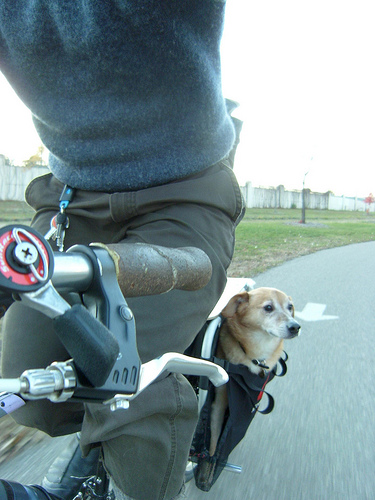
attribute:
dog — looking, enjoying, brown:
[220, 274, 295, 402]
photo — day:
[28, 11, 371, 475]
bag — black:
[189, 375, 276, 460]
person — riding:
[24, 31, 240, 307]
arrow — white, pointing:
[286, 281, 361, 345]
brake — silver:
[39, 340, 230, 395]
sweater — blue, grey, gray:
[16, 10, 214, 162]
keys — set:
[19, 171, 81, 262]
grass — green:
[246, 212, 370, 255]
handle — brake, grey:
[41, 236, 239, 312]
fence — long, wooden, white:
[244, 183, 348, 211]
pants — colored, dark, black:
[79, 180, 230, 366]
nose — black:
[281, 318, 310, 339]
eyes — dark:
[256, 296, 298, 316]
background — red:
[10, 225, 68, 303]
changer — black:
[41, 309, 135, 368]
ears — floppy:
[212, 294, 259, 334]